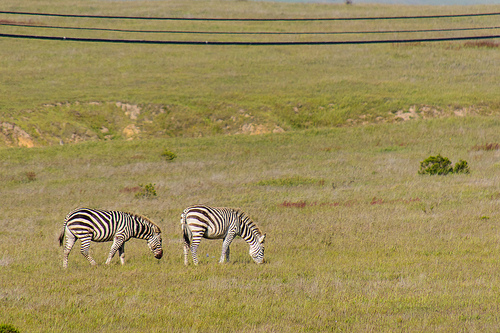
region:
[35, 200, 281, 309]
There are two zebras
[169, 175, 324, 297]
the zebra is grazing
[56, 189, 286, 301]
the zebras have beautiful stripes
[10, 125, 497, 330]
the land appears very flat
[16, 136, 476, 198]
the grass is very green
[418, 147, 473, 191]
there are little bushes in this field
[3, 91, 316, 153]
there are patches of dirt visible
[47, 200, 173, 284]
the zebra looks like a striped horse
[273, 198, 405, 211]
there are red flowers in the field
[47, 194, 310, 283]
the zebras seem peaceful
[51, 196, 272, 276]
Zebras feeding at noon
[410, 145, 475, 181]
A green bush with sharp ends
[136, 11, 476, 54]
Power lines in black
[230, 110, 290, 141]
Light brown rock with sandstone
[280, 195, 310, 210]
Deep reddish-brown grass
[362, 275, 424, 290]
Dry, parched grass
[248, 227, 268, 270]
Zebra head with black and white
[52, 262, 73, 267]
Zebra hoof with black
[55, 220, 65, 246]
Zebra tail with black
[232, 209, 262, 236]
Zebra mane with white and black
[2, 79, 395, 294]
Two zebras out in field.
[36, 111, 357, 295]
Two zebras out in a grassy field.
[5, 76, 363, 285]
Couple of zebras in a field.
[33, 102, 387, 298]
Couple of zebras in a grassy field.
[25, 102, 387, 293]
Couple of zebras together in a field.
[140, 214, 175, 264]
head of a zebra.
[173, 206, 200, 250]
tail of a zebra.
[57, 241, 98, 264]
hind legs of a zebra.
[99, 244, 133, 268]
front legs of a zebra.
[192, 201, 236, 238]
body of a zebra.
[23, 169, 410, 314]
two zebras in a field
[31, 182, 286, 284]
zebras both facing right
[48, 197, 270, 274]
zebras are grazing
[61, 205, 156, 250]
black and white stripes on a zebra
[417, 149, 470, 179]
small green bushes in a field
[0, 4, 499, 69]
power cables above a field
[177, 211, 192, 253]
zebra tail has a black fluffy tip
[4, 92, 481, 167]
a rocky fissure in a field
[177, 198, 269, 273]
zebra is eating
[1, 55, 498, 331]
dry grass in a field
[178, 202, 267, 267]
zebra grazing in open field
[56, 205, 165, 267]
black and white striped zebra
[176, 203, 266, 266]
black and white striped zebra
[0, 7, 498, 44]
black power lines hanging overhead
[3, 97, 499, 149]
creek running through field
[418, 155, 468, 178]
dark green plant growing in field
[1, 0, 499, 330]
grass green, yellow, and brown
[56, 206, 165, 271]
zebra standing behind another zebra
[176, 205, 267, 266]
zebra standing in front of another zebra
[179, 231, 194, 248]
black hair at end of tail